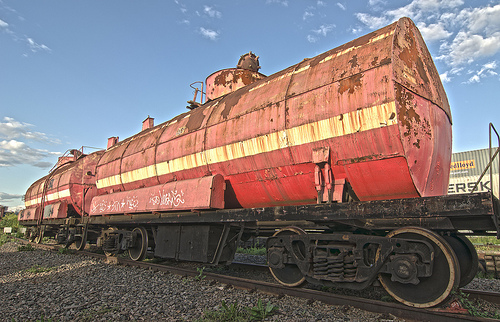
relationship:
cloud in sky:
[182, 5, 219, 41] [1, 0, 499, 206]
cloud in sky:
[352, 1, 500, 89] [1, 0, 499, 206]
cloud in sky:
[3, 116, 71, 171] [1, 0, 499, 206]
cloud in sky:
[2, 6, 53, 56] [1, 0, 499, 206]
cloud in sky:
[364, 1, 480, 61] [1, 0, 499, 206]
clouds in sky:
[2, 116, 63, 169] [1, 0, 499, 206]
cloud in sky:
[196, 25, 221, 42] [1, 0, 499, 206]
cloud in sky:
[313, 21, 335, 38] [1, 0, 499, 206]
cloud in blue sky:
[352, 1, 500, 89] [0, 4, 172, 130]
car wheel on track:
[259, 225, 313, 292] [37, 233, 474, 308]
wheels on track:
[366, 222, 460, 313] [34, 218, 482, 317]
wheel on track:
[92, 224, 123, 253] [20, 238, 471, 309]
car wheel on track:
[269, 227, 314, 292] [155, 252, 324, 308]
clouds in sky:
[16, 60, 49, 89] [4, 0, 484, 178]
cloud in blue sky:
[352, 1, 500, 89] [19, 8, 190, 80]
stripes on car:
[88, 96, 423, 189] [5, 15, 498, 308]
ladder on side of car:
[39, 176, 59, 225] [7, 139, 121, 237]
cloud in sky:
[352, 1, 500, 89] [8, 7, 478, 142]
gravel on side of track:
[16, 257, 201, 320] [18, 218, 468, 313]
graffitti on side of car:
[88, 185, 215, 220] [28, 41, 447, 221]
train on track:
[0, 15, 483, 322] [25, 231, 477, 314]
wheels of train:
[262, 222, 460, 307] [0, 15, 483, 322]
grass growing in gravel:
[203, 299, 279, 319] [183, 283, 284, 320]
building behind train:
[448, 139, 497, 200] [0, 15, 483, 322]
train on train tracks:
[0, 15, 483, 322] [0, 227, 499, 322]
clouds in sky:
[173, 0, 222, 42] [1, 0, 499, 206]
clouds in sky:
[0, 0, 55, 62] [1, 0, 499, 206]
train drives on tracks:
[0, 15, 483, 322] [47, 230, 497, 319]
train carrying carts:
[16, 91, 451, 206] [29, 160, 293, 211]